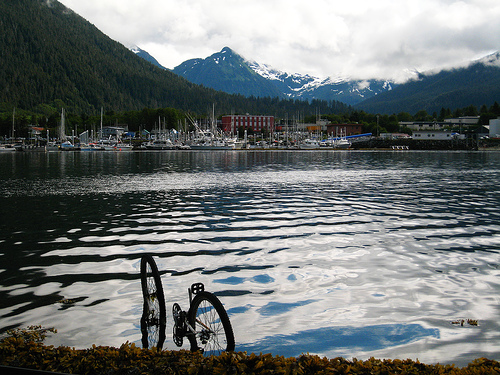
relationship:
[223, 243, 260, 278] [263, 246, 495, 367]
ripples on water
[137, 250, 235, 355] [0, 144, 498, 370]
bicycle in water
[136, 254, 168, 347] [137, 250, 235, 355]
tire of bicycle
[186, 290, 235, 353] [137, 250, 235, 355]
wheel of bicycle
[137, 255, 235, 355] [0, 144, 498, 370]
bicycle in water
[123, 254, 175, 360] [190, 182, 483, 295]
tire in water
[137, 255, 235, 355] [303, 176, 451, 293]
bicycle sticking out of water